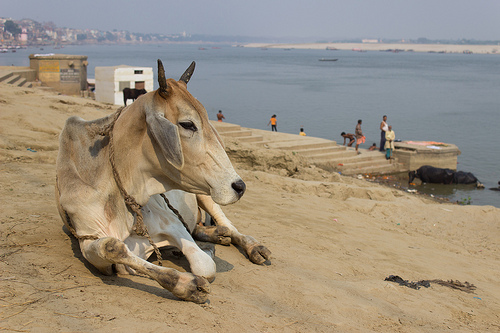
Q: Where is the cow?
A: On a beach.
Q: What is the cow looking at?
A: The water.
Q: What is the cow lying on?
A: Sand.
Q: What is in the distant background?
A: Buildings.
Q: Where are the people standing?
A: On a cement structure.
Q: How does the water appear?
A: Calm.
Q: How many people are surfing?
A: None.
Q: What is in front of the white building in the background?
A: Cow.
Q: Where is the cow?
A: On the beach.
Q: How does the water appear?
A: Calm.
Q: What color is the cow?
A: Light brown.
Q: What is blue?
A: Sky.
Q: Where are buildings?
A: In the distance.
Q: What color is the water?
A: Blue.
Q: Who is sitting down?
A: Cow.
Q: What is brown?
A: Sand.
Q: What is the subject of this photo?
A: A cow.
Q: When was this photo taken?
A: Daytime.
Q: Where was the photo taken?
A: At the beach.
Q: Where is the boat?
A: On the water.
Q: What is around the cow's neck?
A: Rope.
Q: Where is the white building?
A: Behind the cow.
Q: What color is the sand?
A: Brown.